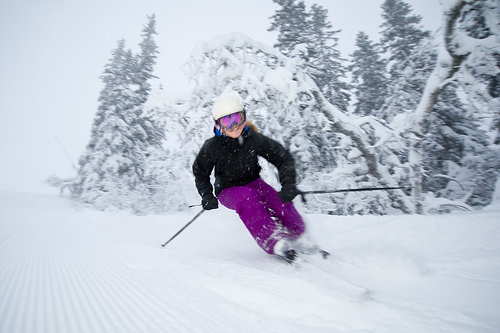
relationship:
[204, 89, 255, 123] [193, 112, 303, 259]
white helmet on skier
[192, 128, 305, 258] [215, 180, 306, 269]
skier wearing purple pants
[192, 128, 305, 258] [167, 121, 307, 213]
skier wearing black coat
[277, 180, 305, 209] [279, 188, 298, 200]
glove on hand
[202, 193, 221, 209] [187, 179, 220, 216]
glove on skier's right hand